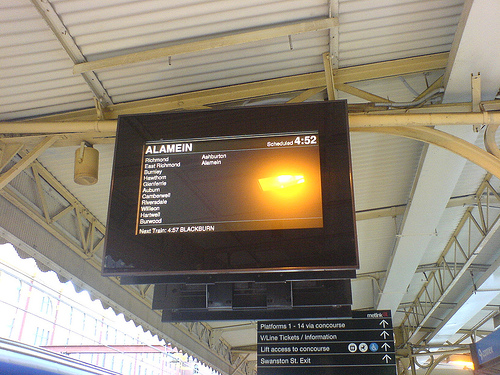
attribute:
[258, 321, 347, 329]
letters — white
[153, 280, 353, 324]
sign — black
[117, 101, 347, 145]
frame — black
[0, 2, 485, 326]
roof — white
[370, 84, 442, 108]
pipe — white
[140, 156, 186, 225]
writing — white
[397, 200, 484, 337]
ceiling supports — white metal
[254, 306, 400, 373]
signage — for directions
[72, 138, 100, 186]
light fixture — not turned on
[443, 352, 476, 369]
light — powered on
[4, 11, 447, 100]
ceiling — steel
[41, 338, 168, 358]
girder — metal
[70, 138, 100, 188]
can — yellow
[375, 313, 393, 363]
arrows — white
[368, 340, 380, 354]
circle — blue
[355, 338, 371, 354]
circle — white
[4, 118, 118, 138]
pipe — yellow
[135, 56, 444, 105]
beam — yellow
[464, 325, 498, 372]
sign — blue